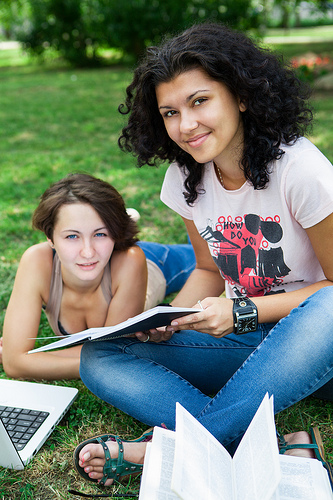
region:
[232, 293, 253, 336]
a person wearing a black watch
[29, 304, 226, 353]
a person holding a book.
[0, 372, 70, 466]
a computer sitting on the ground.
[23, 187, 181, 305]
person laying on the ground.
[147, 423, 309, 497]
an open book sitting on the ground.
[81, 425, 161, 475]
a girl wearing blue sandels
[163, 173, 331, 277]
a girl wearing white shirt.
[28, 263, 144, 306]
a girl wearing a tan tank top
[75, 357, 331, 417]
a girl wearing blue jeans.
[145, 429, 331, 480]
an opened book is on top of a foot.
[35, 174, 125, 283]
the girl is looking at the viewer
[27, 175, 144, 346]
the girl is wearing a tank top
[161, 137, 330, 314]
the girl is wearing a short sleeve shirt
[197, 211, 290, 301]
the shirt has a graphic print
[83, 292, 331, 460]
the girl is wearing jeans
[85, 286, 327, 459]
the jeans are blue in color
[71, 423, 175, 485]
the girl is wearing sandals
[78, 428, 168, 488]
the sandals are green in color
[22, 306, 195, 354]
the girl is holding a book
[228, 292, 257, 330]
the girl is wearing a watch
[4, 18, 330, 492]
The girls are doing homework together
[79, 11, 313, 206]
The girl has dark hair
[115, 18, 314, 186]
The girls hair is black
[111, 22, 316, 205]
The girls hair is very curly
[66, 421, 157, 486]
The girl is wearing sandals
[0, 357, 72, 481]
The girls are using a laptop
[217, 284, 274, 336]
The girl is wearing a watch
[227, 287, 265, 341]
The watch is very big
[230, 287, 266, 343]
The watch has a black band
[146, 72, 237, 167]
The girl has a beautiful smile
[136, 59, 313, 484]
A woman sitting in the green color grass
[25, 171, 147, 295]
A woman laydown in the green color grass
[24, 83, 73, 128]
Green color grass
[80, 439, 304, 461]
A woman wearing pair of green color chappals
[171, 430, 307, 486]
Book kept in front of the woman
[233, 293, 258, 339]
A woman wearing black color wrist watch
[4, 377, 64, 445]
A white color laptop kept in the grass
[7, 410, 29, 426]
Black color keyboard of the laptop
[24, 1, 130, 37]
Trees with green leaves and branches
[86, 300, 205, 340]
A woman holding the note book